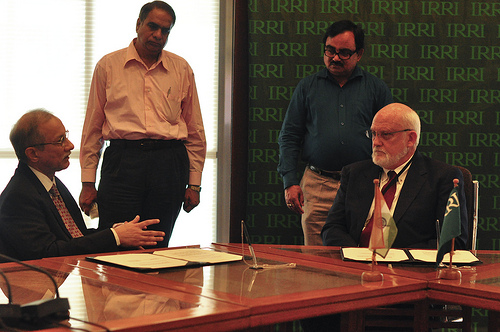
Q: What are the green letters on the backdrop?
A: IRRI.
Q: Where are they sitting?
A: At the table.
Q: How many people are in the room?
A: 4.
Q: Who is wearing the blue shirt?
A: The man in front of the backdrop.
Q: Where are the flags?
A: On the table.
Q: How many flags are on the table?
A: 2.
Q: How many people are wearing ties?
A: Two.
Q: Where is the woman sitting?
A: There is no woman.